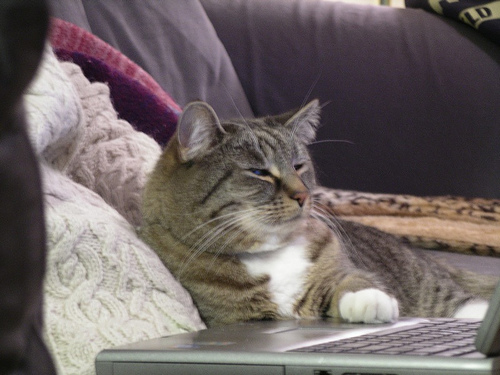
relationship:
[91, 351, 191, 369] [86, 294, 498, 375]
edge of laptop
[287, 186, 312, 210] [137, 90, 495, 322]
nose of cat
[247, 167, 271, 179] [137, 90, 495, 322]
eye of cat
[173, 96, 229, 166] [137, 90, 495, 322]
ear of cat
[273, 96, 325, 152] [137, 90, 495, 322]
ear of cat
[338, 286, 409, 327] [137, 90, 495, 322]
paw of cat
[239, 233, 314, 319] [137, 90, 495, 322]
fur on cat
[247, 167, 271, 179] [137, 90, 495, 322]
eye of kitten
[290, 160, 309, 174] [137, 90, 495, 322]
eye of kitten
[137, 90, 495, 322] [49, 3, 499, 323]
cat on couch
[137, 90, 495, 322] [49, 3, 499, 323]
cat resting on couch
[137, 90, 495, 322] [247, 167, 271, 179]
cat with eye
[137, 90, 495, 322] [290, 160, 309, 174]
cat with eye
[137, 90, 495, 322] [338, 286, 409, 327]
cat with paw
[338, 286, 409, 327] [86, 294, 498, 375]
paw on laptop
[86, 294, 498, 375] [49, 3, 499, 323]
laptop on couch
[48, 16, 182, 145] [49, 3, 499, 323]
blanket on couch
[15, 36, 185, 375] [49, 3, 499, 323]
blanket on couch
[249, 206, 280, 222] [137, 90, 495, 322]
mustaches of cat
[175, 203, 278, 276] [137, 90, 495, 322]
whiskers of cat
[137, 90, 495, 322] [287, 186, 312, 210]
cat has nose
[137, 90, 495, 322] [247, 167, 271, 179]
cat has eye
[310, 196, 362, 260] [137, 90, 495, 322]
whiskers of cat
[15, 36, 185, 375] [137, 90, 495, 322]
blanket behind cat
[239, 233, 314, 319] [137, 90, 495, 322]
chest of cat